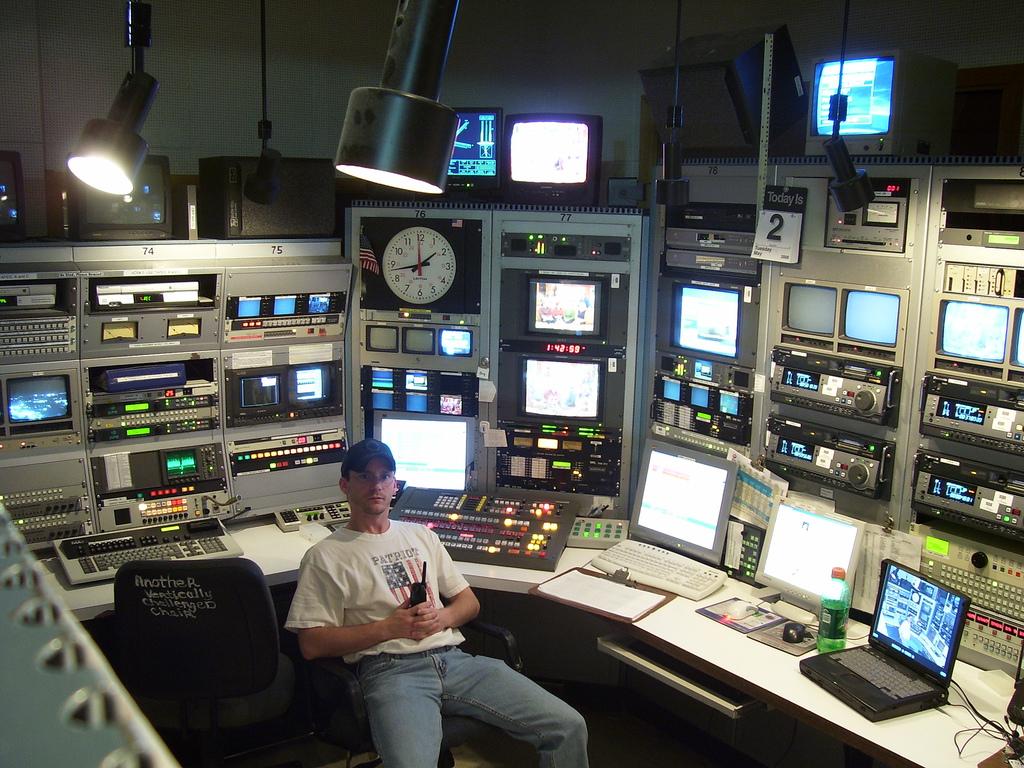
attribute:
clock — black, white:
[363, 215, 477, 314]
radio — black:
[397, 550, 436, 604]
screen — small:
[220, 282, 351, 346]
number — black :
[751, 184, 812, 277]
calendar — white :
[751, 184, 812, 277]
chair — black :
[109, 554, 287, 707]